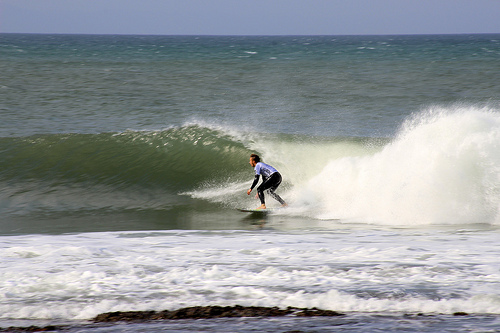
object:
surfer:
[245, 154, 290, 213]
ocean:
[0, 1, 500, 312]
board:
[238, 206, 287, 214]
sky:
[0, 1, 500, 34]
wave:
[0, 103, 500, 226]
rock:
[93, 305, 345, 323]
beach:
[0, 307, 500, 332]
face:
[247, 157, 254, 166]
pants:
[257, 172, 287, 205]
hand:
[247, 188, 254, 196]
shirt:
[247, 163, 278, 188]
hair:
[249, 154, 260, 163]